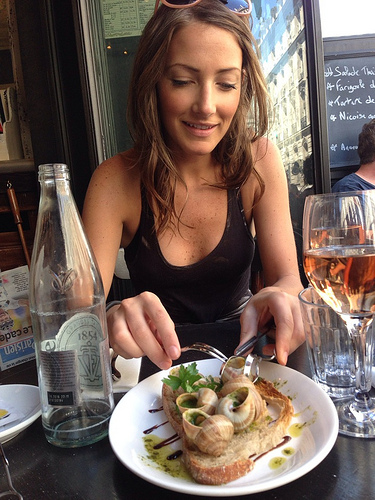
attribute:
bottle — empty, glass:
[27, 145, 129, 455]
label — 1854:
[41, 312, 114, 410]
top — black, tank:
[122, 146, 255, 329]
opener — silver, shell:
[221, 346, 273, 382]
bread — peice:
[121, 373, 323, 478]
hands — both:
[108, 288, 304, 381]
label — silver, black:
[35, 349, 79, 410]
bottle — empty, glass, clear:
[28, 166, 111, 456]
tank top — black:
[101, 167, 277, 276]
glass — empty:
[299, 283, 373, 398]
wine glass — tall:
[301, 190, 373, 441]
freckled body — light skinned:
[155, 185, 229, 264]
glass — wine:
[293, 177, 374, 426]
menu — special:
[325, 63, 374, 117]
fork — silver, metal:
[171, 341, 238, 370]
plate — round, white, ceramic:
[297, 442, 336, 467]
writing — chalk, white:
[320, 65, 373, 153]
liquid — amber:
[300, 244, 373, 317]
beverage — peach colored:
[302, 246, 374, 316]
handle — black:
[230, 323, 279, 361]